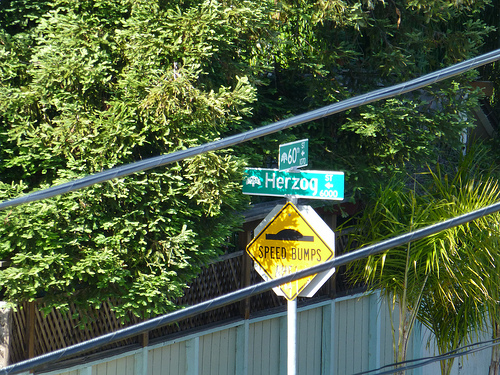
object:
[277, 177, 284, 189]
letter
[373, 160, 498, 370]
palmtree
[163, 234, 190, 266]
branch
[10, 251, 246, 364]
fence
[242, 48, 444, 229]
tree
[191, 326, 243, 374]
wall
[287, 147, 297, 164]
60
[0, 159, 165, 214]
pole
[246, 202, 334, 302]
diamond sign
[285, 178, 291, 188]
letter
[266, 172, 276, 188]
letter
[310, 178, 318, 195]
letter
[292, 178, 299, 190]
letter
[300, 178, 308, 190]
letter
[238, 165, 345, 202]
green signs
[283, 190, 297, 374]
pole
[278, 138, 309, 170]
sign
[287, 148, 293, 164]
white number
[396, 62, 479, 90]
wires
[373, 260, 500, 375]
fence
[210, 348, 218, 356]
part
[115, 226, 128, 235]
part